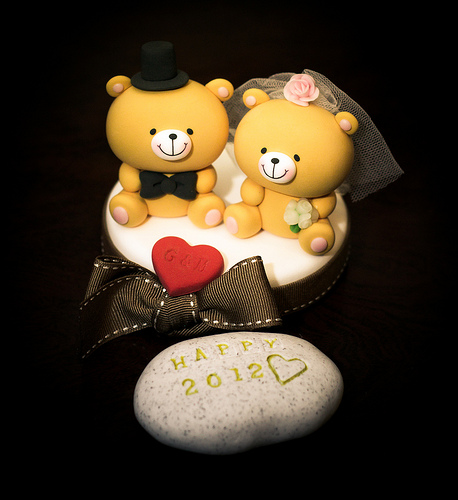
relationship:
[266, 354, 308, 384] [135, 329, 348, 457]
heart hetched in stone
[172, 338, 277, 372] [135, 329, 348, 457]
happy hetched in stone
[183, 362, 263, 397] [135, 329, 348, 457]
2012 etched in stone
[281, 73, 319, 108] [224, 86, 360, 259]
rose on top of bear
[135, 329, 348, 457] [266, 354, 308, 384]
stone has heart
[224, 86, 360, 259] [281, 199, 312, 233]
bear has flower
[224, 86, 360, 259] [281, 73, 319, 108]
bear has rose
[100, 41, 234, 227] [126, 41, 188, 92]
bear has top hat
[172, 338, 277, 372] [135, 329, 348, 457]
happy on top of stone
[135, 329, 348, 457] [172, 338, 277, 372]
stone engraved with happy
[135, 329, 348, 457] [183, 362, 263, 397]
stone engraved with 2012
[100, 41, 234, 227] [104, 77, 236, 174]
bear has head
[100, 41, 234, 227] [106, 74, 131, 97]
bear has ear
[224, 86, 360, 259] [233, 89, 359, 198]
bear ha head